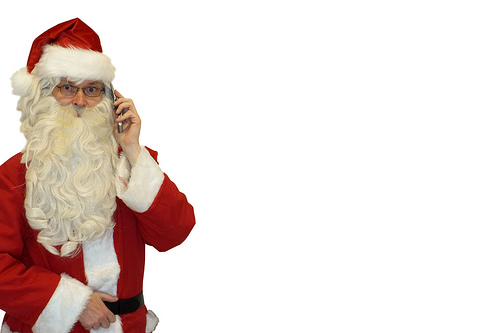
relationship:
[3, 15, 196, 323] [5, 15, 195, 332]
santa wearing red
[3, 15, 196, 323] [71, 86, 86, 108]
santa has a nose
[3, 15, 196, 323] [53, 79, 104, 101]
santa wearing glasses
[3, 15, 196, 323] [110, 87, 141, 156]
santa has a left hand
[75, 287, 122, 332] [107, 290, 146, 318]
hand on belt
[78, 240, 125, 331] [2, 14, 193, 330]
white on clothes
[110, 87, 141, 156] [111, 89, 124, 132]
hand holding cell phone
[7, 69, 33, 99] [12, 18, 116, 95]
ball on hat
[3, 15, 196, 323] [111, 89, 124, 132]
santa using cell phone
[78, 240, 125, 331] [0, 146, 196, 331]
trim on jacket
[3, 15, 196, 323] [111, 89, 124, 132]
santa using phone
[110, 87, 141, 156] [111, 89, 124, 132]
hand holding phone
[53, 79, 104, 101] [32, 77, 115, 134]
glasses on face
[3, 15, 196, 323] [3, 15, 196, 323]
suit wearing suit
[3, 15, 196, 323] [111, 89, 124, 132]
santa holding phone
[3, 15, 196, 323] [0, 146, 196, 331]
santa wearing a jacket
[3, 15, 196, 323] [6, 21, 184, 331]
man wearing santa outfit